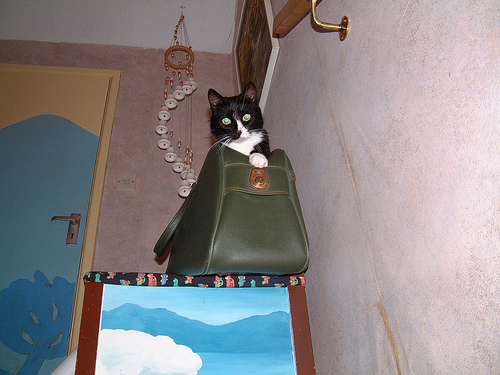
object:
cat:
[205, 80, 272, 169]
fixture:
[329, 14, 352, 44]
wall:
[275, 0, 500, 375]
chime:
[151, 13, 205, 200]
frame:
[229, 0, 282, 118]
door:
[0, 71, 113, 375]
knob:
[48, 179, 90, 250]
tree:
[0, 267, 79, 375]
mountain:
[0, 108, 98, 295]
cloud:
[92, 323, 204, 375]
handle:
[51, 212, 82, 246]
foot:
[249, 152, 270, 169]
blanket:
[82, 271, 307, 289]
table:
[70, 267, 316, 375]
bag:
[151, 142, 310, 280]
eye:
[220, 117, 232, 126]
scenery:
[93, 287, 297, 375]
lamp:
[272, 8, 341, 38]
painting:
[228, 0, 284, 110]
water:
[193, 352, 292, 375]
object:
[159, 6, 198, 72]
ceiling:
[0, 0, 243, 57]